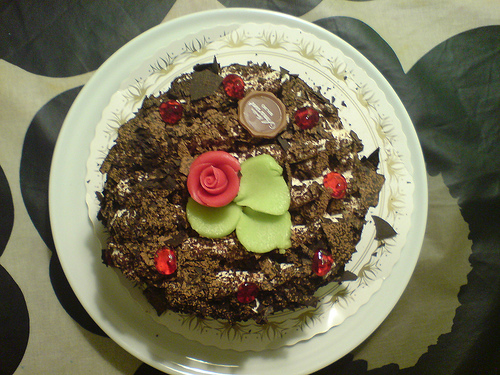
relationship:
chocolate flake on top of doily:
[372, 214, 395, 249] [82, 20, 419, 348]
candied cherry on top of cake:
[320, 166, 351, 197] [96, 61, 383, 324]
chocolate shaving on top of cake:
[181, 62, 215, 100] [96, 61, 383, 324]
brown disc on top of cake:
[231, 89, 291, 137] [96, 61, 383, 324]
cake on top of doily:
[96, 61, 383, 324] [82, 20, 419, 348]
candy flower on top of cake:
[187, 151, 242, 209] [96, 61, 383, 324]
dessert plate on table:
[50, 7, 424, 370] [1, 2, 492, 369]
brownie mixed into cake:
[123, 119, 198, 156] [96, 61, 383, 324]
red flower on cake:
[320, 171, 351, 198] [96, 61, 383, 324]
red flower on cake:
[311, 246, 339, 272] [96, 61, 383, 324]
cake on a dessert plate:
[96, 61, 383, 324] [50, 7, 424, 375]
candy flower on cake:
[187, 151, 242, 209] [96, 61, 383, 324]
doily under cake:
[82, 20, 419, 348] [96, 61, 383, 324]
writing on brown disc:
[246, 99, 280, 130] [231, 89, 291, 137]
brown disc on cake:
[231, 89, 291, 137] [96, 61, 383, 324]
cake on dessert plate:
[96, 61, 383, 324] [50, 7, 424, 375]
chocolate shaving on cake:
[181, 62, 215, 100] [96, 61, 383, 324]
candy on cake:
[158, 96, 185, 124] [96, 61, 383, 324]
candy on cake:
[222, 73, 250, 100] [96, 61, 383, 324]